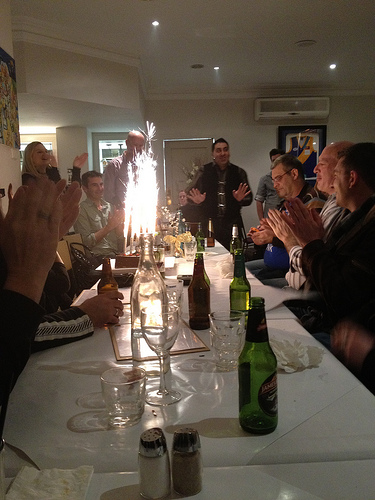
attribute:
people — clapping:
[45, 140, 357, 280]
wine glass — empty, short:
[136, 303, 186, 410]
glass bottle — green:
[230, 295, 288, 434]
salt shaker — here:
[133, 430, 171, 498]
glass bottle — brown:
[184, 251, 215, 333]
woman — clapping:
[18, 140, 96, 179]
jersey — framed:
[280, 129, 320, 176]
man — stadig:
[180, 134, 257, 233]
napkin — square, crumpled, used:
[6, 462, 101, 499]